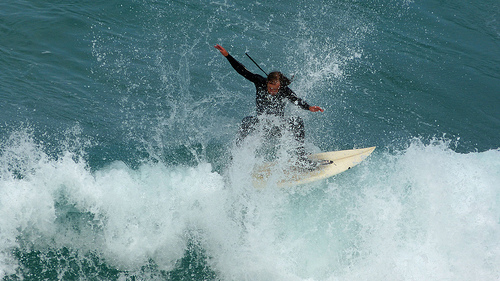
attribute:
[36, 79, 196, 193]
water — droplets, splashing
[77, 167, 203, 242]
wave — large, white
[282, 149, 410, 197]
surfboard — thin, cream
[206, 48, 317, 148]
wet suit — black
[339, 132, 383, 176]
tip — pointed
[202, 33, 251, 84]
arm — extended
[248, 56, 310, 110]
hair — blowing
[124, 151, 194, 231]
waves — good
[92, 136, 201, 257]
waves — big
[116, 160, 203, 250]
waves — nice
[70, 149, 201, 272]
waves — huge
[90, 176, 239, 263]
waves — awesome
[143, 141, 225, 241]
waves — ocean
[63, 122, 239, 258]
waves — great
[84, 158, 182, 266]
waves — huge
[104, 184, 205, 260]
waves — beautiful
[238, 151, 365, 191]
surfboard — white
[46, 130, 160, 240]
water — blue/green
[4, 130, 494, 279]
foam — white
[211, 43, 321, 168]
man — wet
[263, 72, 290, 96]
head — wet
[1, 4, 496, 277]
sea — white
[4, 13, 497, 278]
spray — white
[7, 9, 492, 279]
ocean — blue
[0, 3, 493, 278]
water — blue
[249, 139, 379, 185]
surfboard — beige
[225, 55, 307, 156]
wetsuit — black